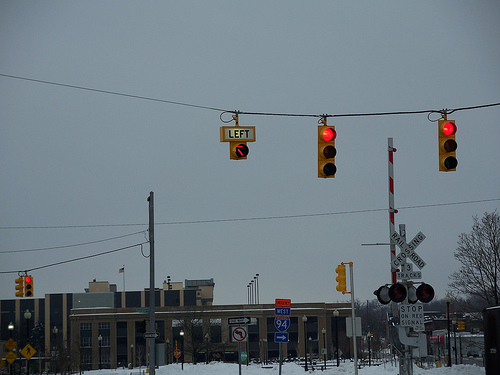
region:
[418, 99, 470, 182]
a traffic light on right side of wire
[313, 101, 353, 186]
a traffic light on left side of wire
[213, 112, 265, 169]
a traffic light sign with an arrow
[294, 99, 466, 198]
two a traffic lights are on red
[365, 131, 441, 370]
a white and red pole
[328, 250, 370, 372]
a traffic light on a pole is yellow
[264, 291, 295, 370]
signs to signal the number of a road 94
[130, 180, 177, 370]
pole holding a string that supports a traffic light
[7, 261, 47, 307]
two traffic lights sid by side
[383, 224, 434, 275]
a sign that forms an X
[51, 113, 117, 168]
this is the sky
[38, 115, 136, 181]
the sky is white in color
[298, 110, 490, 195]
these are two traffic lights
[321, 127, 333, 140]
the light is red in color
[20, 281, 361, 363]
this is a building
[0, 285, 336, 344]
the building is big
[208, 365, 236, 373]
this is the ground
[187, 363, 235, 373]
the ground is full of snow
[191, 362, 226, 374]
the snow is white in color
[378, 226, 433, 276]
this is a railway crossing line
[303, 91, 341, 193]
yellow stoplight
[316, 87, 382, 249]
yellow stoplight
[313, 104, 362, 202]
yellow stoplight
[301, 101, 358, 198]
yellow stoplightyellow stoplight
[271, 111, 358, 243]
the traffic light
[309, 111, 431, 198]
the traffic light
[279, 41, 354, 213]
the traffic light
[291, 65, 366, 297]
the traffic light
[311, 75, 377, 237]
the traffic light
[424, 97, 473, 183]
the signal lights showing red signal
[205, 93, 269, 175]
the signal light showing left signal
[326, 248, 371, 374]
the white color pole showing signal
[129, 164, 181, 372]
the pole in the middle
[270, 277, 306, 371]
the blue color sign board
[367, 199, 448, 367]
the white color sign board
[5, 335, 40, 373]
the yellow color sign board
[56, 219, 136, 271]
the electrical wires on the poles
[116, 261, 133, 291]
the national flag on the top of the building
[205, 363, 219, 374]
the white color snow on the ground